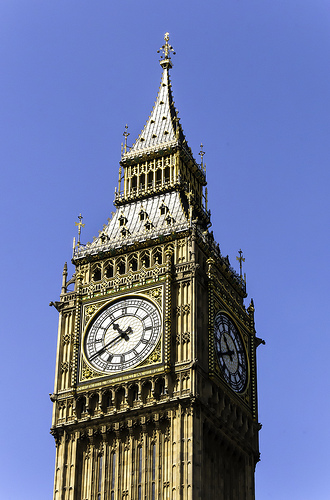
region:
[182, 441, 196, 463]
erdge of a tower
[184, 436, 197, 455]
edge of a towr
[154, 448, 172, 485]
part f a line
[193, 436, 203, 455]
part of a loine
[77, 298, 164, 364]
round analog clock on tower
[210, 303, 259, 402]
round analog clock on tower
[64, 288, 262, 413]
two round analog clocks on tower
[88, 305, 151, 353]
hands on the clock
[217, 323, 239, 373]
hands on the clock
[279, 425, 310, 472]
area of blue cloudless sky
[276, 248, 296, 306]
area of blue cloudless sky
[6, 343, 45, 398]
area of blue cloudless sky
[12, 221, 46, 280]
area of blue cloudless sky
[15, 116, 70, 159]
area of blue cloudless sky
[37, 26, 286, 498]
This is a tower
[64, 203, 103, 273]
This is a tower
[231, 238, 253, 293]
This is a tower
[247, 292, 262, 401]
This is a tower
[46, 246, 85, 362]
This is a tower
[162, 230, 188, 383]
This is a tower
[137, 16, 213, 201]
This is a tower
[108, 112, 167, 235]
This is a tower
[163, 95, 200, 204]
This is a tower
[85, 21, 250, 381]
This is a tower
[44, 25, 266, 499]
an up close shot of Big Ben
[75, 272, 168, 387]
a large clock on a tower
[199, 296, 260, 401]
a large clock on a tower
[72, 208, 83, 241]
an ornamental pole on a towel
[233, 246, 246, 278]
an ornamental pole on a towel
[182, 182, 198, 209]
an ornamental pole on a towel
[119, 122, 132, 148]
an ornamental pole on a towel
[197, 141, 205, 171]
an ornamental pole on a towel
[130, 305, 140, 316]
the roman numeral 1 on a clock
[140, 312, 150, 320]
the roman numeral 2 on a clock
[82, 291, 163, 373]
The face of a clock on a building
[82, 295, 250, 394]
Two clock faces on the sides of a tower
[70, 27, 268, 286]
The roof of a tower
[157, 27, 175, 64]
Steeple on top of a tower.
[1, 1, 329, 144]
A clear, blue sky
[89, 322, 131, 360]
Minute and hour hands on a clock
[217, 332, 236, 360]
The hands of a clock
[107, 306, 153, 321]
Numbers on the face of a clock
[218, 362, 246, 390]
Numerals on the face of a clock